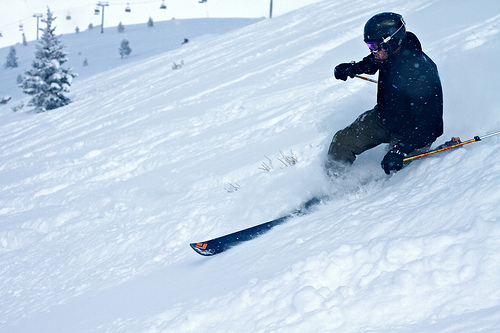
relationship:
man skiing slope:
[326, 12, 462, 181] [7, 0, 494, 332]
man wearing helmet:
[313, 5, 452, 192] [359, 15, 409, 47]